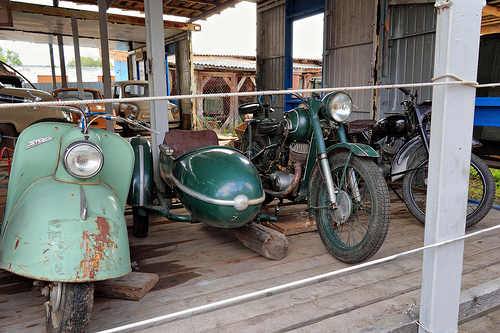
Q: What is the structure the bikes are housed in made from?
A: Wood.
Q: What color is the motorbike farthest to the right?
A: Green.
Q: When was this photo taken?
A: Daytime.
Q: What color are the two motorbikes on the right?
A: Green.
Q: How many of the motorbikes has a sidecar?
A: 1.